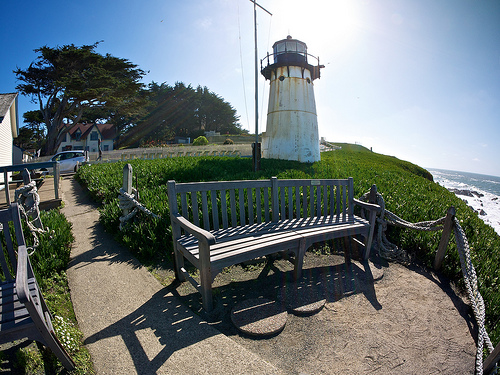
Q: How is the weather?
A: It is cloudless.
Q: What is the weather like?
A: It is cloudless.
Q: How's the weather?
A: It is cloudless.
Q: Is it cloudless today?
A: Yes, it is cloudless.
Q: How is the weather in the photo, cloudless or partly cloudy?
A: It is cloudless.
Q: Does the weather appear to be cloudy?
A: No, it is cloudless.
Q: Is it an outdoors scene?
A: Yes, it is outdoors.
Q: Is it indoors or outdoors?
A: It is outdoors.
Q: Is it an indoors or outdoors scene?
A: It is outdoors.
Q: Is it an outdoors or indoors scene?
A: It is outdoors.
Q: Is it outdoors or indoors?
A: It is outdoors.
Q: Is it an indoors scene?
A: No, it is outdoors.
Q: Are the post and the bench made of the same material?
A: Yes, both the post and the bench are made of wood.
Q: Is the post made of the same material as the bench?
A: Yes, both the post and the bench are made of wood.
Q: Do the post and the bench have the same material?
A: Yes, both the post and the bench are made of wood.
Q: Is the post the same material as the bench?
A: Yes, both the post and the bench are made of wood.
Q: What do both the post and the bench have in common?
A: The material, both the post and the bench are wooden.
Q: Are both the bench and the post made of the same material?
A: Yes, both the bench and the post are made of wood.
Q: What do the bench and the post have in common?
A: The material, both the bench and the post are wooden.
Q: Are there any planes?
A: No, there are no planes.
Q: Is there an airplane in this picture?
A: No, there are no airplanes.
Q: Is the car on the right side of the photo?
A: No, the car is on the left of the image.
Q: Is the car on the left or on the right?
A: The car is on the left of the image.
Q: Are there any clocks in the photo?
A: No, there are no clocks.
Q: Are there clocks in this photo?
A: No, there are no clocks.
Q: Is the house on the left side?
A: Yes, the house is on the left of the image.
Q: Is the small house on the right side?
A: No, the house is on the left of the image.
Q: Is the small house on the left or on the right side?
A: The house is on the left of the image.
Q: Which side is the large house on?
A: The house is on the left of the image.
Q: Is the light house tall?
A: Yes, the light house is tall.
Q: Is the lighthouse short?
A: No, the lighthouse is tall.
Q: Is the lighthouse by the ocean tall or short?
A: The lighthouse is tall.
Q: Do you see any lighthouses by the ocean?
A: Yes, there is a lighthouse by the ocean.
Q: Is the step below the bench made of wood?
A: Yes, the step is below the bench.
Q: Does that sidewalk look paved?
A: Yes, the sidewalk is paved.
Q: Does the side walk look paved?
A: Yes, the side walk is paved.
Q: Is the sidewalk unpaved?
A: No, the sidewalk is paved.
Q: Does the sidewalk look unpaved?
A: No, the sidewalk is paved.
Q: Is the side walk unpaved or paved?
A: The side walk is paved.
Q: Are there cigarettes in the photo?
A: No, there are no cigarettes.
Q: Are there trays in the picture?
A: No, there are no trays.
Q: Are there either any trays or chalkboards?
A: No, there are no trays or chalkboards.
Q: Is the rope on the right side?
A: Yes, the rope is on the right of the image.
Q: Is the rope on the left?
A: No, the rope is on the right of the image.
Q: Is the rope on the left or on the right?
A: The rope is on the right of the image.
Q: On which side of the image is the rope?
A: The rope is on the right of the image.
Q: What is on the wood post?
A: The rope is on the post.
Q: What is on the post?
A: The rope is on the post.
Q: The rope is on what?
A: The rope is on the post.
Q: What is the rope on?
A: The rope is on the post.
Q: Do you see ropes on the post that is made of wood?
A: Yes, there is a rope on the post.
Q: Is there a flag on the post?
A: No, there is a rope on the post.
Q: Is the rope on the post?
A: Yes, the rope is on the post.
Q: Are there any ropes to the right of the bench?
A: Yes, there is a rope to the right of the bench.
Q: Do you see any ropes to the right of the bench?
A: Yes, there is a rope to the right of the bench.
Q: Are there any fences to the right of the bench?
A: No, there is a rope to the right of the bench.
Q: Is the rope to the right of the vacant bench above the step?
A: Yes, the rope is to the right of the bench.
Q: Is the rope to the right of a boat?
A: No, the rope is to the right of the bench.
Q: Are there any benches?
A: Yes, there is a bench.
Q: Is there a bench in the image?
A: Yes, there is a bench.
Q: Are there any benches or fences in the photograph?
A: Yes, there is a bench.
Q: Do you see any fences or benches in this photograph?
A: Yes, there is a bench.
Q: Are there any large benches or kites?
A: Yes, there is a large bench.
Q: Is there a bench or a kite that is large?
A: Yes, the bench is large.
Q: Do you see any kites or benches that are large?
A: Yes, the bench is large.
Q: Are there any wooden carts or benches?
A: Yes, there is a wood bench.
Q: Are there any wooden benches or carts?
A: Yes, there is a wood bench.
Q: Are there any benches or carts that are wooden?
A: Yes, the bench is wooden.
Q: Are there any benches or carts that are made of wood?
A: Yes, the bench is made of wood.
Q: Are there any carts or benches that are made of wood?
A: Yes, the bench is made of wood.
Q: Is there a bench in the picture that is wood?
A: Yes, there is a wood bench.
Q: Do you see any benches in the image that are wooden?
A: Yes, there is a bench that is wooden.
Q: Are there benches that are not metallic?
A: Yes, there is a wooden bench.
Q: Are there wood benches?
A: Yes, there is a bench that is made of wood.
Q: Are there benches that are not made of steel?
A: Yes, there is a bench that is made of wood.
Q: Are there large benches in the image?
A: Yes, there is a large bench.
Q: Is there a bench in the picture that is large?
A: Yes, there is a bench that is large.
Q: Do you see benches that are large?
A: Yes, there is a bench that is large.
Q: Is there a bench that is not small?
A: Yes, there is a large bench.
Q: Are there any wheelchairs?
A: No, there are no wheelchairs.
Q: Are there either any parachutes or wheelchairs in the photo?
A: No, there are no wheelchairs or parachutes.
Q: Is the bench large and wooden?
A: Yes, the bench is large and wooden.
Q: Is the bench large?
A: Yes, the bench is large.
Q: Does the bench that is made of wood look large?
A: Yes, the bench is large.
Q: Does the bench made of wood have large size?
A: Yes, the bench is large.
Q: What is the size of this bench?
A: The bench is large.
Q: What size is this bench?
A: The bench is large.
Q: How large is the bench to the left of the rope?
A: The bench is large.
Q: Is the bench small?
A: No, the bench is large.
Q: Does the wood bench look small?
A: No, the bench is large.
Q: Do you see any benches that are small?
A: No, there is a bench but it is large.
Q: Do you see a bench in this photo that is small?
A: No, there is a bench but it is large.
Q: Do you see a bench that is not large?
A: No, there is a bench but it is large.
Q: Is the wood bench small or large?
A: The bench is large.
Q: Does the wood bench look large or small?
A: The bench is large.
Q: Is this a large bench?
A: Yes, this is a large bench.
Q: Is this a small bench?
A: No, this is a large bench.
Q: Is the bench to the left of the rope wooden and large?
A: Yes, the bench is wooden and large.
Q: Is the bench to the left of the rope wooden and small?
A: No, the bench is wooden but large.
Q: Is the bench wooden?
A: Yes, the bench is wooden.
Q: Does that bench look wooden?
A: Yes, the bench is wooden.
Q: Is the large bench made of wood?
A: Yes, the bench is made of wood.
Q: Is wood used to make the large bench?
A: Yes, the bench is made of wood.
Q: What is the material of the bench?
A: The bench is made of wood.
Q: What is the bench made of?
A: The bench is made of wood.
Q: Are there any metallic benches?
A: No, there is a bench but it is wooden.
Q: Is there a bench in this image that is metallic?
A: No, there is a bench but it is wooden.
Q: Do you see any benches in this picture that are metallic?
A: No, there is a bench but it is wooden.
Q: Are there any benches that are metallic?
A: No, there is a bench but it is wooden.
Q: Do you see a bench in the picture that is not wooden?
A: No, there is a bench but it is wooden.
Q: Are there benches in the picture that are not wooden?
A: No, there is a bench but it is wooden.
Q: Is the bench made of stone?
A: No, the bench is made of wood.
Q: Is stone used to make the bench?
A: No, the bench is made of wood.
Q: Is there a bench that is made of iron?
A: No, there is a bench but it is made of wood.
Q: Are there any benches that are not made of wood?
A: No, there is a bench but it is made of wood.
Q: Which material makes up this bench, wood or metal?
A: The bench is made of wood.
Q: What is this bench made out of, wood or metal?
A: The bench is made of wood.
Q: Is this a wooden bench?
A: Yes, this is a wooden bench.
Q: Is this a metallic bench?
A: No, this is a wooden bench.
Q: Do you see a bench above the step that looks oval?
A: Yes, there is a bench above the step.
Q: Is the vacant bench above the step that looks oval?
A: Yes, the bench is above the step.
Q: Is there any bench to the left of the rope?
A: Yes, there is a bench to the left of the rope.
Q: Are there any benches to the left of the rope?
A: Yes, there is a bench to the left of the rope.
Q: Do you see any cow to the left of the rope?
A: No, there is a bench to the left of the rope.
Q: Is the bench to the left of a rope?
A: Yes, the bench is to the left of a rope.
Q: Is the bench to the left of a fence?
A: No, the bench is to the left of a rope.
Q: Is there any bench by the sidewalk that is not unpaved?
A: Yes, there is a bench by the sidewalk.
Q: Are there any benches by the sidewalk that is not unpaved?
A: Yes, there is a bench by the sidewalk.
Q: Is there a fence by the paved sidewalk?
A: No, there is a bench by the sidewalk.